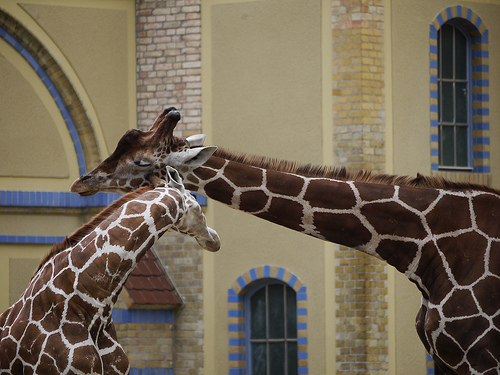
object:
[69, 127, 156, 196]
face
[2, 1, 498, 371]
building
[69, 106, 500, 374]
giraffe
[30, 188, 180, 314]
neck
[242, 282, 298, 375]
window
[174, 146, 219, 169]
ear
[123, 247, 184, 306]
shingles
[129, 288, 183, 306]
tile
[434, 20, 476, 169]
window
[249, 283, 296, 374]
bars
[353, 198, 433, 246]
spots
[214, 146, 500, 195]
hair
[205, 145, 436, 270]
neck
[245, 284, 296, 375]
frame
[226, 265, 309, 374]
trim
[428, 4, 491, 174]
trim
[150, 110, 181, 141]
horns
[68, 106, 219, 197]
giraffe's head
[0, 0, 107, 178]
arch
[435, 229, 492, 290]
spot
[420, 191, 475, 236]
spot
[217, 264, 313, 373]
border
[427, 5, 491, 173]
border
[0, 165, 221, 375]
giraffe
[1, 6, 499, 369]
wall